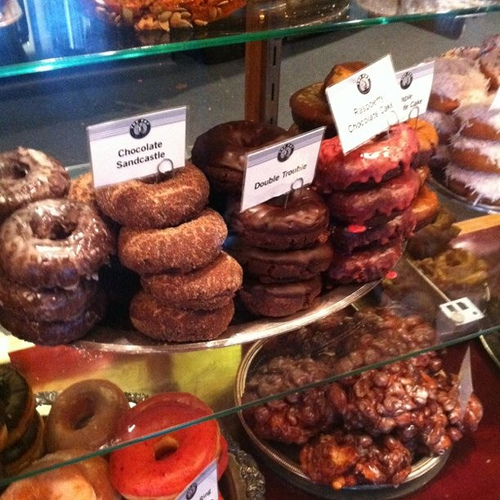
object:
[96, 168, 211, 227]
brown pastries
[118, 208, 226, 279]
brown pastries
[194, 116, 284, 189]
brown pastries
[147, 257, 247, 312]
brown pastries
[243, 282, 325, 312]
brown pastries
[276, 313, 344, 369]
donut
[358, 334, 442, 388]
donut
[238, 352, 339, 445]
donut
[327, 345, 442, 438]
donut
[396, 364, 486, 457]
donut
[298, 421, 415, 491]
donut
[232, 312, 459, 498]
tin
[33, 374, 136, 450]
donut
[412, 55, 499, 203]
iced donuts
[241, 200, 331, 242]
donut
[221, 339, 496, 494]
metal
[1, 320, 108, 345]
donut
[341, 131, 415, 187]
glaze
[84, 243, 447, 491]
container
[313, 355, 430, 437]
pastries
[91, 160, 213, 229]
donut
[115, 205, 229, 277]
donut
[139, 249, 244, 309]
donut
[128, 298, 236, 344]
donut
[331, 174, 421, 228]
red donut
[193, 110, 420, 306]
donut stack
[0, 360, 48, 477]
pastry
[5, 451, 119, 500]
pastry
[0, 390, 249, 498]
platter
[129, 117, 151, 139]
black design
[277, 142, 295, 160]
black design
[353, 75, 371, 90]
black design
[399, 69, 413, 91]
black design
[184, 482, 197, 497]
black design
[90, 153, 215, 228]
pastry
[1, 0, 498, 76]
glass shelf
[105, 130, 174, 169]
doughnut sign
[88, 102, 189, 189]
sandcastle sign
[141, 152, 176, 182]
clip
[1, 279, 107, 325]
donut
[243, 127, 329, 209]
tag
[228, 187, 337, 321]
pastries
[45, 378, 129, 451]
doughnuts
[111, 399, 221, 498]
doughnuts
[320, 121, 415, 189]
doughnuts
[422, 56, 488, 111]
doughnuts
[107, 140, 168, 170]
pastry name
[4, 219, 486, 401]
shelf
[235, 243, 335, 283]
donut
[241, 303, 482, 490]
apple fritters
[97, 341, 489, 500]
bottom shelf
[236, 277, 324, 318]
donut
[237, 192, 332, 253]
donut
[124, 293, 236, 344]
donut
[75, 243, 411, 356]
plate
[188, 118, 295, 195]
pastries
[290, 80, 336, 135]
pastries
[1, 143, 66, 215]
pastries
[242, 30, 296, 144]
pole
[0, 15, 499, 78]
racks